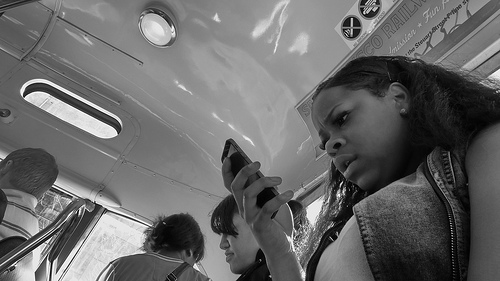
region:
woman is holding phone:
[210, 126, 295, 227]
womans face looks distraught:
[296, 79, 398, 186]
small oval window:
[13, 55, 132, 151]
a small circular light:
[124, 6, 239, 61]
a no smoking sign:
[324, 10, 369, 45]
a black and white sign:
[341, 13, 458, 70]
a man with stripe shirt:
[6, 139, 64, 266]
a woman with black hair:
[196, 186, 281, 268]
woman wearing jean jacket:
[402, 146, 474, 268]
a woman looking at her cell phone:
[217, 46, 498, 268]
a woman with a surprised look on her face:
[300, 52, 427, 197]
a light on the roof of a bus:
[128, 4, 184, 53]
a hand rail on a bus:
[1, 194, 88, 276]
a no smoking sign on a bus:
[337, 14, 365, 44]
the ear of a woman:
[384, 82, 413, 117]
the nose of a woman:
[320, 134, 347, 156]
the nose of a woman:
[215, 236, 232, 251]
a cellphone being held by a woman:
[210, 137, 292, 222]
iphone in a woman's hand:
[220, 138, 281, 218]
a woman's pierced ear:
[387, 83, 412, 116]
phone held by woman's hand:
[220, 138, 312, 280]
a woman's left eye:
[335, 107, 352, 132]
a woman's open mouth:
[330, 151, 359, 178]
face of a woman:
[209, 200, 255, 275]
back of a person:
[98, 207, 214, 279]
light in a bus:
[137, 6, 174, 48]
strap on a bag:
[161, 262, 191, 279]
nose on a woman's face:
[218, 236, 230, 251]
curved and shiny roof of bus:
[12, 1, 497, 163]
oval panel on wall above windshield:
[5, 55, 227, 247]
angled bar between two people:
[0, 140, 202, 276]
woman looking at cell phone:
[211, 50, 491, 272]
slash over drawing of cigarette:
[332, 0, 357, 45]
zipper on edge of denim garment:
[345, 150, 470, 270]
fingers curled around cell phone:
[215, 135, 295, 235]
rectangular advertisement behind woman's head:
[295, 1, 495, 156]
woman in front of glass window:
[75, 190, 205, 275]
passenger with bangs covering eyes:
[206, 185, 267, 276]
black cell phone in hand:
[211, 131, 286, 220]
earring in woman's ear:
[402, 105, 414, 112]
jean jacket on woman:
[353, 175, 450, 279]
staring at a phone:
[194, 34, 461, 229]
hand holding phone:
[196, 129, 290, 244]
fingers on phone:
[208, 148, 290, 210]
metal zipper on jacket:
[442, 216, 468, 251]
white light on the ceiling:
[124, 10, 188, 48]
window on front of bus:
[20, 71, 125, 143]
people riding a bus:
[0, 48, 447, 258]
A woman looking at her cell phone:
[216, 50, 498, 238]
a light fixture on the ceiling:
[134, 4, 180, 49]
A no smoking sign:
[334, 12, 366, 42]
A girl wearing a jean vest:
[302, 45, 489, 271]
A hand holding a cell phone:
[220, 136, 294, 223]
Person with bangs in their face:
[208, 195, 256, 272]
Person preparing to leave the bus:
[92, 211, 209, 279]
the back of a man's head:
[2, 143, 59, 203]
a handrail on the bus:
[41, 199, 83, 254]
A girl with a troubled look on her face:
[310, 53, 443, 189]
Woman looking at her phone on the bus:
[187, 118, 294, 245]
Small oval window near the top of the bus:
[8, 60, 143, 195]